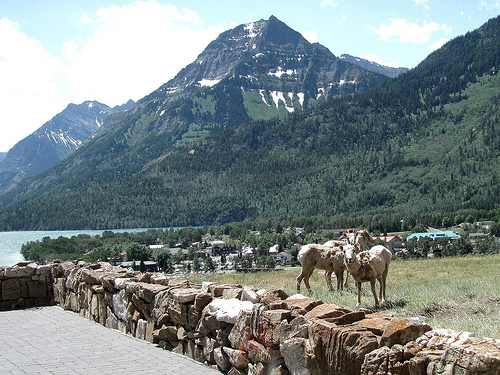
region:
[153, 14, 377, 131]
Snow covered mountain top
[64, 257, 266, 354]
Wall made up of rocks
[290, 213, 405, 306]
Animals grouped together in grassy field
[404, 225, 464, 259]
Building with blue roof top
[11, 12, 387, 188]
Mountain peaks dusted with snow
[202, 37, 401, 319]
Animals standing together with mountain backdrop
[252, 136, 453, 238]
Tree lined mountain side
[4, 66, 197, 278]
Body of water at the foot of a mountain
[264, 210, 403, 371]
Animals standing near a rock wall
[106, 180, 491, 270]
Village situated near water and mountains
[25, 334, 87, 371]
The pavement is made from brick.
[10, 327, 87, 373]
The pavement is light in color.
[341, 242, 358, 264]
The sheeps eyes are black.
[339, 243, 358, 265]
The sheeps eyes are small.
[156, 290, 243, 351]
The wall is made from rocks.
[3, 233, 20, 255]
The blue water is in the background.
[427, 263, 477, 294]
The grass is green.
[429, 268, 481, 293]
The grass is long.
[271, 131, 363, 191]
The hill in the backgound is green.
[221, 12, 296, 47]
The peak of the mountain has snow.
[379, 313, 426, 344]
stone used on wall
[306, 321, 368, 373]
stone used on wall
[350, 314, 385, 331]
stone used on wall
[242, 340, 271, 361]
stone used on wall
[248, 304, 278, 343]
stone used on wall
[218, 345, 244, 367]
stone used on wall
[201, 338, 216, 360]
stone used on wall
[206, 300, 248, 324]
stone used on wall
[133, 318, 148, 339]
stone used on wall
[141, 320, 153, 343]
stone used on wall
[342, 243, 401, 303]
a wooly sheep in a field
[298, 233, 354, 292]
a wooly sheep in a field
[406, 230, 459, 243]
residential houses in the distance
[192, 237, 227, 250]
residential houses in the distance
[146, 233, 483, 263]
residential houses in the distance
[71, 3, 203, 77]
white clouds in the sky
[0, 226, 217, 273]
a big lake in the vallly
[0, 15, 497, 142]
big snow capped mountain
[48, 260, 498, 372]
a big rock wall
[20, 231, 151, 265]
tree that are next to lake